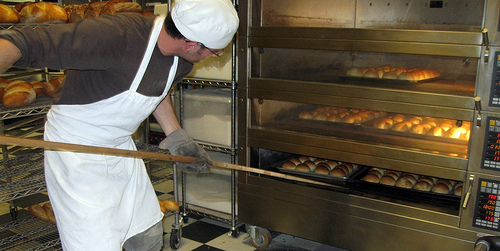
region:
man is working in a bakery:
[3, 0, 240, 242]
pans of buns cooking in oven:
[273, 151, 464, 209]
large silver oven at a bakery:
[237, 2, 498, 247]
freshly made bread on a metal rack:
[0, 73, 58, 109]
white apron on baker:
[44, 12, 183, 249]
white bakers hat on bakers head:
[171, 0, 241, 50]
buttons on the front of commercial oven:
[471, 175, 498, 233]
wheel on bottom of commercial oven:
[245, 223, 272, 248]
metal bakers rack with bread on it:
[0, 0, 184, 247]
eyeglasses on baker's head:
[183, 37, 226, 59]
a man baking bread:
[0, 1, 240, 250]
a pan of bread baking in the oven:
[274, 156, 361, 182]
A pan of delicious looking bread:
[360, 167, 465, 207]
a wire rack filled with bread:
[0, 1, 145, 249]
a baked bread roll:
[327, 168, 347, 179]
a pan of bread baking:
[296, 102, 386, 132]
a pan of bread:
[339, 61, 441, 86]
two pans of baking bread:
[297, 104, 468, 144]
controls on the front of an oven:
[482, 115, 499, 170]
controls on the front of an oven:
[472, 172, 499, 231]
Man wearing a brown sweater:
[0, 1, 242, 245]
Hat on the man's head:
[164, 2, 249, 54]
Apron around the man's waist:
[49, 15, 181, 248]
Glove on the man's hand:
[160, 127, 222, 174]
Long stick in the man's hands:
[1, 122, 340, 198]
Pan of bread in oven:
[277, 144, 359, 188]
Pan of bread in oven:
[355, 159, 470, 214]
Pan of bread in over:
[337, 52, 440, 96]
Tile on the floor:
[163, 206, 258, 249]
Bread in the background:
[3, 0, 162, 137]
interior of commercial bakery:
[3, 3, 493, 245]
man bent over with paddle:
[2, 1, 318, 248]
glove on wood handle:
[157, 125, 210, 175]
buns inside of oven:
[277, 61, 472, 193]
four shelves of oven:
[244, 3, 483, 217]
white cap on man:
[172, 1, 239, 48]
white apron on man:
[44, 15, 179, 249]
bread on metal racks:
[1, 5, 68, 248]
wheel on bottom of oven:
[247, 225, 273, 249]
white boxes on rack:
[177, 65, 236, 224]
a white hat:
[168, 2, 241, 51]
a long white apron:
[43, 10, 180, 249]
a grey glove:
[157, 128, 218, 179]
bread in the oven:
[279, 54, 470, 200]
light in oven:
[436, 113, 468, 155]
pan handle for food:
[1, 133, 331, 190]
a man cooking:
[2, 0, 242, 245]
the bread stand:
[1, 0, 240, 246]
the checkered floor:
[161, 205, 244, 250]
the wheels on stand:
[166, 225, 183, 246]